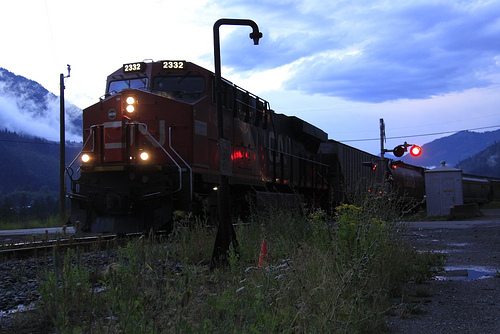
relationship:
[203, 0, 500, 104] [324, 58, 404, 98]
cloud in sky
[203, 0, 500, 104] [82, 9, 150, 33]
cloud in sky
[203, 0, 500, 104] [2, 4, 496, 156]
cloud in sky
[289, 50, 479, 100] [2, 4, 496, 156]
cloud in sky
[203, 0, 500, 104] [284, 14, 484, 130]
cloud in sky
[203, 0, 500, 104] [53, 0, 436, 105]
cloud in sky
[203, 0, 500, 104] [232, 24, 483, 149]
cloud in sky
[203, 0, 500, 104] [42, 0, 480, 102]
cloud in sky